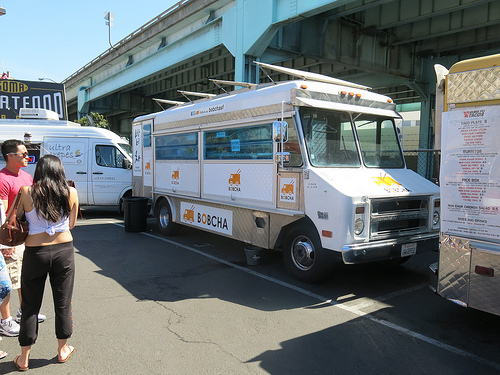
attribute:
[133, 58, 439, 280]
bus — parked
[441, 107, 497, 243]
menu — large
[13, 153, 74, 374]
woman — standing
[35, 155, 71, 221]
hair — long, brown, black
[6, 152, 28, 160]
sunglasses — black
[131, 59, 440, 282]
truck — light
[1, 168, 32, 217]
shirt — red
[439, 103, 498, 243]
sign — white, large, silver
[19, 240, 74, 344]
pants — black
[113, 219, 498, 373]
line — long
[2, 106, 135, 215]
van — white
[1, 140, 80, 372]
people — standing